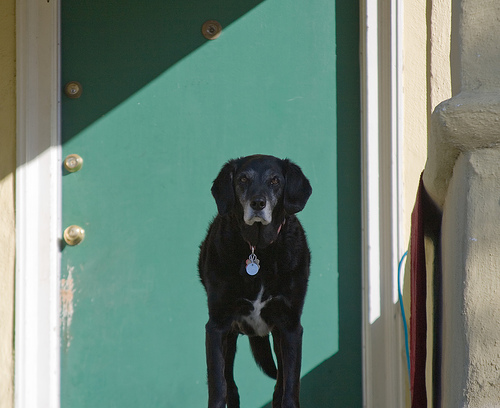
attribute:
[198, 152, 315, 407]
dog — black, old, white, standing, looking, mad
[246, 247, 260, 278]
dog tag — metal, blue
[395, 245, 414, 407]
wire — blue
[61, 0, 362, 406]
door — green, ugly, faded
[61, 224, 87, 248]
door knob — gold, bronze, yellow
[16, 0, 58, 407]
molding — white, thick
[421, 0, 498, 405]
support beam — concrete, tan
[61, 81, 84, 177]
deadbolt locks — bronze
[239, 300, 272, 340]
underbelly — white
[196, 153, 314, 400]
hair — black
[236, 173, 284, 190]
eyes — brown, open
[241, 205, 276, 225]
mouth — grey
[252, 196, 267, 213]
nose — black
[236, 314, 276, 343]
stomach — white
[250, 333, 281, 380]
tail — black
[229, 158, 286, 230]
face — white, black